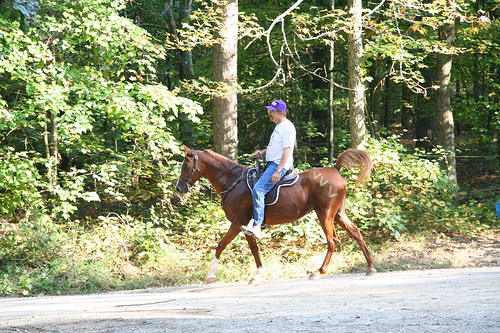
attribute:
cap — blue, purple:
[265, 97, 289, 116]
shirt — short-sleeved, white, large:
[266, 119, 296, 170]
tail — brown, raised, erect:
[334, 146, 375, 195]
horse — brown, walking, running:
[176, 148, 382, 283]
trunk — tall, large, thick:
[210, 1, 239, 165]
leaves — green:
[0, 0, 497, 237]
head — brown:
[174, 148, 202, 197]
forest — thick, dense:
[1, 1, 497, 249]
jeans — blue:
[251, 160, 292, 226]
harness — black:
[222, 168, 248, 208]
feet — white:
[205, 255, 266, 287]